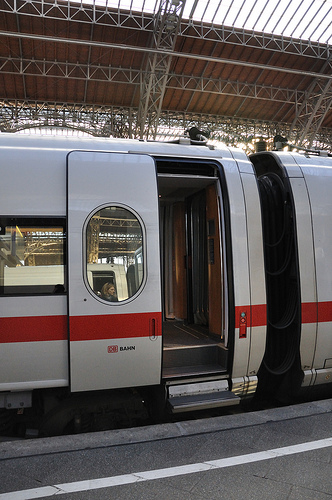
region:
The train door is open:
[73, 160, 273, 393]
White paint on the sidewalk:
[175, 459, 217, 490]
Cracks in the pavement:
[245, 462, 290, 489]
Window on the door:
[77, 193, 151, 315]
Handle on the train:
[138, 312, 163, 344]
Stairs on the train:
[143, 355, 271, 427]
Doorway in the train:
[156, 216, 217, 354]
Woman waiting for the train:
[94, 259, 144, 315]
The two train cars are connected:
[208, 135, 330, 347]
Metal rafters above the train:
[111, 118, 234, 137]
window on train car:
[78, 194, 155, 309]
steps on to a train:
[149, 331, 253, 427]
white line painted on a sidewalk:
[20, 420, 329, 495]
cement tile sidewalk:
[102, 433, 328, 495]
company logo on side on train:
[94, 342, 149, 360]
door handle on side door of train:
[139, 310, 162, 361]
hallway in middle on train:
[178, 188, 238, 344]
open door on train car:
[48, 143, 275, 454]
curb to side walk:
[1, 415, 328, 463]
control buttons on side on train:
[234, 300, 251, 354]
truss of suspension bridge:
[52, 63, 64, 74]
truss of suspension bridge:
[23, 58, 39, 73]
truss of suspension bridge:
[131, 17, 140, 27]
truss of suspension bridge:
[182, 25, 189, 34]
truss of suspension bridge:
[45, 3, 56, 13]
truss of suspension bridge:
[222, 29, 236, 38]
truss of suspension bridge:
[242, 35, 253, 45]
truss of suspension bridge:
[268, 41, 273, 45]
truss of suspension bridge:
[256, 85, 263, 97]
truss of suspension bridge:
[219, 83, 231, 90]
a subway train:
[10, 142, 328, 426]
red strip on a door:
[9, 310, 161, 348]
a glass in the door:
[82, 202, 151, 303]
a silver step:
[176, 374, 241, 418]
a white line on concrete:
[160, 439, 304, 483]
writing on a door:
[102, 340, 142, 355]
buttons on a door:
[239, 308, 248, 342]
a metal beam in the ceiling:
[136, 55, 177, 128]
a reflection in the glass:
[91, 257, 131, 302]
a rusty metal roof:
[174, 50, 291, 104]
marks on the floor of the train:
[170, 315, 206, 347]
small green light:
[235, 305, 252, 319]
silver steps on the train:
[163, 369, 235, 415]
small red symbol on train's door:
[103, 341, 120, 355]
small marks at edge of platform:
[168, 414, 194, 446]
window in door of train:
[78, 202, 157, 315]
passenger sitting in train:
[93, 275, 125, 297]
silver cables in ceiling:
[114, 31, 194, 98]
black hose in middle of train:
[246, 165, 311, 280]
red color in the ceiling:
[189, 62, 266, 96]